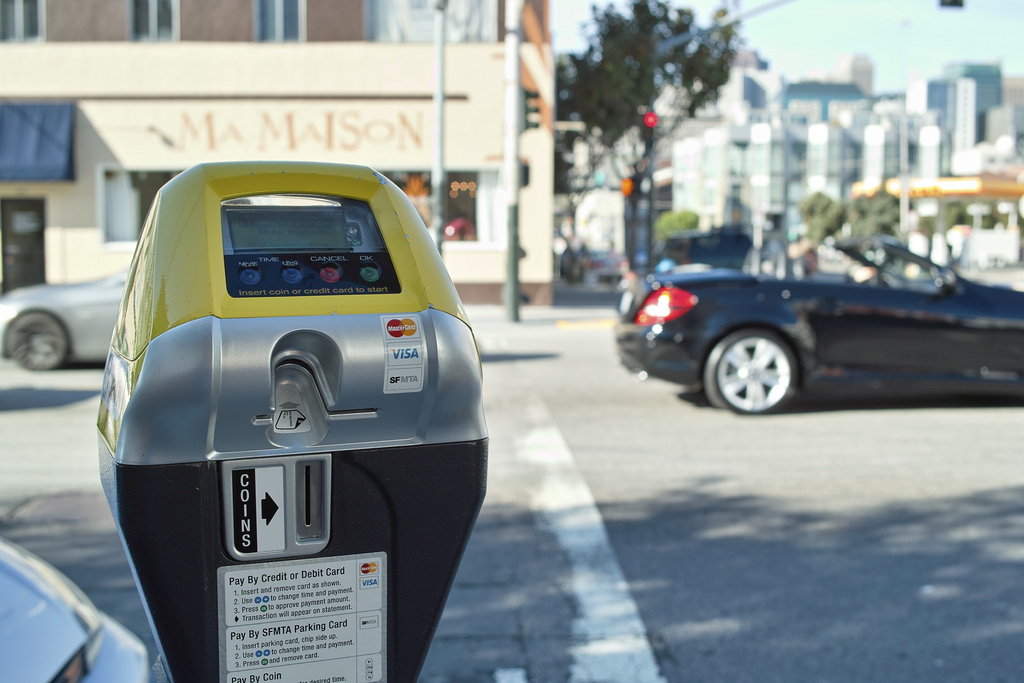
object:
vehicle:
[610, 229, 1024, 414]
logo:
[384, 317, 420, 340]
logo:
[388, 342, 423, 366]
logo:
[388, 369, 423, 391]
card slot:
[254, 329, 382, 447]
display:
[219, 191, 402, 297]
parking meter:
[96, 160, 493, 683]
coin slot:
[217, 453, 330, 560]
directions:
[217, 552, 389, 683]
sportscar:
[616, 233, 1024, 418]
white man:
[785, 237, 820, 280]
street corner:
[551, 284, 619, 308]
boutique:
[0, 37, 520, 313]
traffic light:
[643, 112, 660, 130]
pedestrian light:
[620, 177, 635, 196]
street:
[0, 304, 1024, 683]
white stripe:
[507, 395, 665, 683]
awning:
[0, 99, 79, 183]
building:
[0, 0, 555, 307]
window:
[255, 0, 307, 42]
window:
[128, 170, 481, 243]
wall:
[0, 42, 556, 99]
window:
[102, 169, 178, 242]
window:
[280, 0, 300, 45]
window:
[0, 0, 43, 46]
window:
[129, 0, 181, 41]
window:
[399, 169, 479, 242]